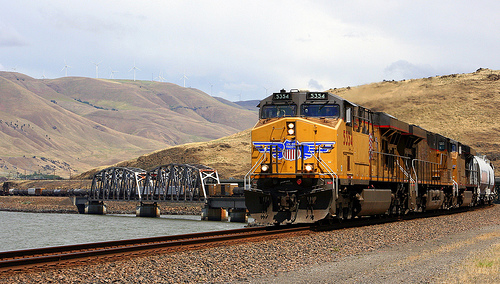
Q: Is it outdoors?
A: Yes, it is outdoors.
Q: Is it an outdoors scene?
A: Yes, it is outdoors.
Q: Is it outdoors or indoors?
A: It is outdoors.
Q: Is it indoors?
A: No, it is outdoors.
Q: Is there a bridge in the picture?
A: Yes, there is a bridge.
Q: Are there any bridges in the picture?
A: Yes, there is a bridge.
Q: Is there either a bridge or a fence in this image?
A: Yes, there is a bridge.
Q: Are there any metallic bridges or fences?
A: Yes, there is a metal bridge.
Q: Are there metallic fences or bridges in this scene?
A: Yes, there is a metal bridge.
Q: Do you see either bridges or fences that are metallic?
A: Yes, the bridge is metallic.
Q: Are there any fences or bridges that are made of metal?
A: Yes, the bridge is made of metal.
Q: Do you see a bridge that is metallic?
A: Yes, there is a metal bridge.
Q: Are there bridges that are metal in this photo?
A: Yes, there is a metal bridge.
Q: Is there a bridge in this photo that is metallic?
A: Yes, there is a bridge that is metallic.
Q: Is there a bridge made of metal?
A: Yes, there is a bridge that is made of metal.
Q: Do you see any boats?
A: No, there are no boats.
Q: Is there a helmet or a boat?
A: No, there are no boats or helmets.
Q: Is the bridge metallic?
A: Yes, the bridge is metallic.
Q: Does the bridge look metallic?
A: Yes, the bridge is metallic.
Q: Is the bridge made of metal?
A: Yes, the bridge is made of metal.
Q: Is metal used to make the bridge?
A: Yes, the bridge is made of metal.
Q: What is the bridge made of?
A: The bridge is made of metal.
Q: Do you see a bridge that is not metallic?
A: No, there is a bridge but it is metallic.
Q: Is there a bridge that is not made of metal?
A: No, there is a bridge but it is made of metal.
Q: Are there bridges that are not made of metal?
A: No, there is a bridge but it is made of metal.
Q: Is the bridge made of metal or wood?
A: The bridge is made of metal.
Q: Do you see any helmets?
A: No, there are no helmets.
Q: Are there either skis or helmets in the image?
A: No, there are no helmets or skis.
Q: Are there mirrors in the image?
A: No, there are no mirrors.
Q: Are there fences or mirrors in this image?
A: No, there are no mirrors or fences.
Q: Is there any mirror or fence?
A: No, there are no mirrors or fences.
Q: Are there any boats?
A: No, there are no boats.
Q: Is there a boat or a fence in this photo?
A: No, there are no boats or fences.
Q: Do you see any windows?
A: Yes, there are windows.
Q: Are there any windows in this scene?
A: Yes, there are windows.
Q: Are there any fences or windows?
A: Yes, there are windows.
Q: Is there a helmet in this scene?
A: No, there are no helmets.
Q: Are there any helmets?
A: No, there are no helmets.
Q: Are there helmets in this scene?
A: No, there are no helmets.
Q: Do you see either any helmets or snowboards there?
A: No, there are no helmets or snowboards.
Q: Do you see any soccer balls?
A: No, there are no soccer balls.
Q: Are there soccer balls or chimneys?
A: No, there are no soccer balls or chimneys.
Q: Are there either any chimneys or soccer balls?
A: No, there are no soccer balls or chimneys.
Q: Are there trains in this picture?
A: Yes, there is a train.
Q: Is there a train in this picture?
A: Yes, there is a train.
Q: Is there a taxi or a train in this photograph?
A: Yes, there is a train.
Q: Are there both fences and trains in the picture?
A: No, there is a train but no fences.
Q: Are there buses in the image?
A: No, there are no buses.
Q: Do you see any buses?
A: No, there are no buses.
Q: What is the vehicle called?
A: The vehicle is a train.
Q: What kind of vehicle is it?
A: The vehicle is a train.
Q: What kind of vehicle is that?
A: This is a train.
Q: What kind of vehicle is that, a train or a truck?
A: This is a train.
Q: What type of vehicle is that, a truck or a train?
A: This is a train.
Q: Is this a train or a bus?
A: This is a train.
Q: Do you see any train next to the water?
A: Yes, there is a train next to the water.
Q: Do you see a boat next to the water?
A: No, there is a train next to the water.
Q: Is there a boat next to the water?
A: No, there is a train next to the water.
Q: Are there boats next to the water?
A: No, there is a train next to the water.